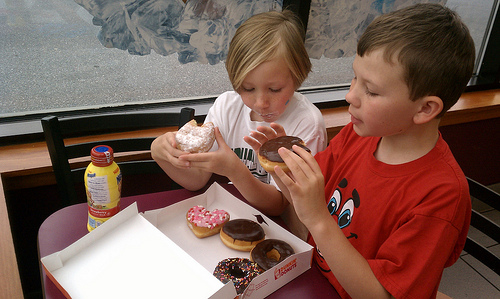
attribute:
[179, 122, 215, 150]
donut — round, white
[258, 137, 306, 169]
donut — chocolate, brown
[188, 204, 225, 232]
heart shaped donut — pink, red white, colorful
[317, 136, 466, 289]
shirt — red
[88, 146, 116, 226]
bottle — chocolate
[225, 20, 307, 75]
hair — blonde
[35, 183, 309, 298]
donut box — white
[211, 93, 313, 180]
shirt — white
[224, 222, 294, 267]
donuts — chocolate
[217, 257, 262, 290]
donut — brown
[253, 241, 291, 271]
donut — chocolate